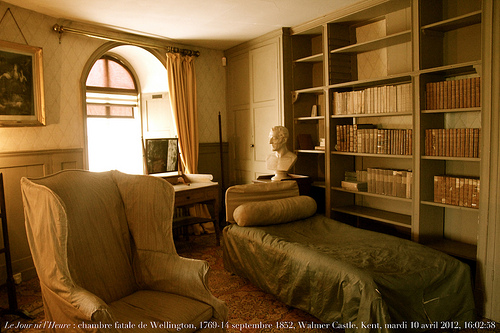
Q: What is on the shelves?
A: Books.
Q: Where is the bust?
A: In front of shelves.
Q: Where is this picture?
A: Walmer Castle.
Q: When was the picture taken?
A: 2012.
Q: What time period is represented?
A: 1852.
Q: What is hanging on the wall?
A: Picture.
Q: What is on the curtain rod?
A: Curtain.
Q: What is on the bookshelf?
A: Books.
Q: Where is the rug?
A: On the ground.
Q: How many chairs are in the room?
A: One.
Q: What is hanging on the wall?
A: A painting.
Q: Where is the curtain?
A: On the window.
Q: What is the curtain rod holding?
A: A curtain.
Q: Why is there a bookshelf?
A: To hold books.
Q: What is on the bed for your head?
A: A pillow.